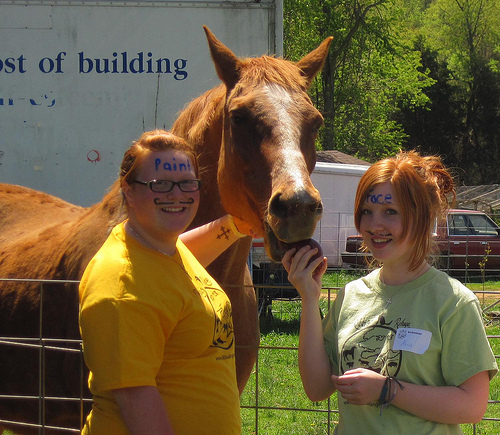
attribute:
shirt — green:
[326, 256, 498, 430]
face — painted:
[144, 149, 204, 234]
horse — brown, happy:
[4, 24, 333, 429]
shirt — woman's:
[76, 240, 252, 432]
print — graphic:
[200, 297, 234, 360]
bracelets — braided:
[380, 375, 399, 402]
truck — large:
[323, 167, 353, 242]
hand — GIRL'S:
[280, 244, 330, 300]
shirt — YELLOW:
[73, 222, 241, 424]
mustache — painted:
[155, 194, 193, 212]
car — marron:
[333, 199, 496, 288]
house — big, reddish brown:
[4, 4, 327, 262]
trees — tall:
[324, 6, 498, 160]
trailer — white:
[315, 154, 369, 270]